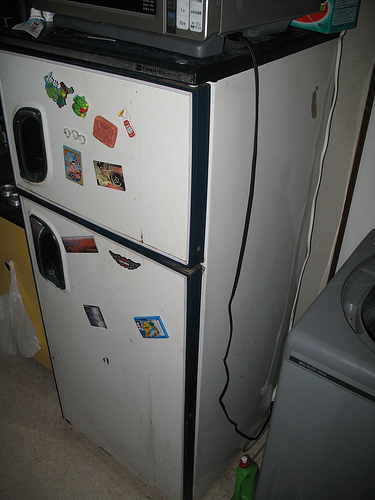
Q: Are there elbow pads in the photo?
A: No, there are no elbow pads.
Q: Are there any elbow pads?
A: No, there are no elbow pads.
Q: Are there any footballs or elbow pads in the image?
A: No, there are no elbow pads or footballs.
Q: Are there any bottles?
A: Yes, there is a bottle.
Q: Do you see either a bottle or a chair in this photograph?
A: Yes, there is a bottle.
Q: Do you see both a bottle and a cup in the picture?
A: No, there is a bottle but no cups.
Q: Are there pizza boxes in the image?
A: No, there are no pizza boxes.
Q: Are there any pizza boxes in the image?
A: No, there are no pizza boxes.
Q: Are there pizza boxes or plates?
A: No, there are no pizza boxes or plates.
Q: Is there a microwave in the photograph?
A: Yes, there is a microwave.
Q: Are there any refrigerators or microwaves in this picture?
A: Yes, there is a microwave.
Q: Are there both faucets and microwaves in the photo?
A: No, there is a microwave but no faucets.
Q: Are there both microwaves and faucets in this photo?
A: No, there is a microwave but no faucets.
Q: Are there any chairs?
A: No, there are no chairs.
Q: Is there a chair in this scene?
A: No, there are no chairs.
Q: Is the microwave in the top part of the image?
A: Yes, the microwave is in the top of the image.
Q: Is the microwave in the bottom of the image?
A: No, the microwave is in the top of the image.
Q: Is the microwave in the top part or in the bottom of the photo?
A: The microwave is in the top of the image.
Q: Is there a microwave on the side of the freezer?
A: Yes, there is a microwave on the side of the freezer.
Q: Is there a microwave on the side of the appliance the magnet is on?
A: Yes, there is a microwave on the side of the freezer.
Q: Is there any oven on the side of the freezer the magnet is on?
A: No, there is a microwave on the side of the refrigerator.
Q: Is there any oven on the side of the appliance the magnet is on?
A: No, there is a microwave on the side of the refrigerator.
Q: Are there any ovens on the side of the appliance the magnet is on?
A: No, there is a microwave on the side of the refrigerator.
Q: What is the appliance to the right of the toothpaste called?
A: The appliance is a microwave.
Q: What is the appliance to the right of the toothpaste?
A: The appliance is a microwave.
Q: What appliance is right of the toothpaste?
A: The appliance is a microwave.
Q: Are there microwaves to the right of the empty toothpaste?
A: Yes, there is a microwave to the right of the toothpaste.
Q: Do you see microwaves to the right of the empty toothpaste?
A: Yes, there is a microwave to the right of the toothpaste.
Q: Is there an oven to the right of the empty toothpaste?
A: No, there is a microwave to the right of the toothpaste.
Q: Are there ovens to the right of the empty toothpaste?
A: No, there is a microwave to the right of the toothpaste.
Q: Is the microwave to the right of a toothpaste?
A: Yes, the microwave is to the right of a toothpaste.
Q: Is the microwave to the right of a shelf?
A: No, the microwave is to the right of a toothpaste.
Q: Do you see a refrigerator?
A: Yes, there is a refrigerator.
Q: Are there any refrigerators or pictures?
A: Yes, there is a refrigerator.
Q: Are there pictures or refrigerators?
A: Yes, there is a refrigerator.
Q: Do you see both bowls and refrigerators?
A: No, there is a refrigerator but no bowls.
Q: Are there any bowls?
A: No, there are no bowls.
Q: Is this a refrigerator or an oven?
A: This is a refrigerator.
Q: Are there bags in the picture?
A: Yes, there is a bag.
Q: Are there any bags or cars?
A: Yes, there is a bag.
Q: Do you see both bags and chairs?
A: No, there is a bag but no chairs.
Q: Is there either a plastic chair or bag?
A: Yes, there is a plastic bag.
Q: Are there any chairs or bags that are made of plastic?
A: Yes, the bag is made of plastic.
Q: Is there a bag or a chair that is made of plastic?
A: Yes, the bag is made of plastic.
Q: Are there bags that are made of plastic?
A: Yes, there is a bag that is made of plastic.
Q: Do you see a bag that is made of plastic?
A: Yes, there is a bag that is made of plastic.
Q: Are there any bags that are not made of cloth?
A: Yes, there is a bag that is made of plastic.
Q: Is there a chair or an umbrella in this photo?
A: No, there are no chairs or umbrellas.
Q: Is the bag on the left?
A: Yes, the bag is on the left of the image.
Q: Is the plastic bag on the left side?
A: Yes, the bag is on the left of the image.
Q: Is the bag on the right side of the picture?
A: No, the bag is on the left of the image.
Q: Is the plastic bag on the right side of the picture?
A: No, the bag is on the left of the image.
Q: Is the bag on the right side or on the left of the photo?
A: The bag is on the left of the image.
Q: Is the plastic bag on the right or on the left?
A: The bag is on the left of the image.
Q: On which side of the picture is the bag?
A: The bag is on the left of the image.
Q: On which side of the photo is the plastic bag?
A: The bag is on the left of the image.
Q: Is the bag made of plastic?
A: Yes, the bag is made of plastic.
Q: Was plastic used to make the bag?
A: Yes, the bag is made of plastic.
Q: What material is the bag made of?
A: The bag is made of plastic.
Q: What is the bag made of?
A: The bag is made of plastic.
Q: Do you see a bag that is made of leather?
A: No, there is a bag but it is made of plastic.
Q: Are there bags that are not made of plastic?
A: No, there is a bag but it is made of plastic.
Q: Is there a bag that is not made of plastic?
A: No, there is a bag but it is made of plastic.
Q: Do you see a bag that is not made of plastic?
A: No, there is a bag but it is made of plastic.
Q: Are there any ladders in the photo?
A: No, there are no ladders.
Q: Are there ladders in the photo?
A: No, there are no ladders.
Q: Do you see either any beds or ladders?
A: No, there are no ladders or beds.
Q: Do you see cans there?
A: No, there are no cans.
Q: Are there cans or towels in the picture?
A: No, there are no cans or towels.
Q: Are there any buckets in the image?
A: No, there are no buckets.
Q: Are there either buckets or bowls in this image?
A: No, there are no buckets or bowls.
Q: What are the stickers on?
A: The stickers are on the freezer.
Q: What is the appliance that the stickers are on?
A: The appliance is a refrigerator.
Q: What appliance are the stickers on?
A: The stickers are on the refrigerator.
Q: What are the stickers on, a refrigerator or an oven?
A: The stickers are on a refrigerator.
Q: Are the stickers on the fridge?
A: Yes, the stickers are on the fridge.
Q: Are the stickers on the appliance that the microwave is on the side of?
A: Yes, the stickers are on the fridge.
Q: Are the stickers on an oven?
A: No, the stickers are on the fridge.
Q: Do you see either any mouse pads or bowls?
A: No, there are no bowls or mouse pads.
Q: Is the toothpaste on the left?
A: Yes, the toothpaste is on the left of the image.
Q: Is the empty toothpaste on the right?
A: No, the toothpaste is on the left of the image.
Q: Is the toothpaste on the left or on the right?
A: The toothpaste is on the left of the image.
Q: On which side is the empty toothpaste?
A: The toothpaste is on the left of the image.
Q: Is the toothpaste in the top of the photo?
A: Yes, the toothpaste is in the top of the image.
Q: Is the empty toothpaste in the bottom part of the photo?
A: No, the toothpaste is in the top of the image.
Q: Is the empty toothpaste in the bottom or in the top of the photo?
A: The toothpaste is in the top of the image.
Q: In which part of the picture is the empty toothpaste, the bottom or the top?
A: The toothpaste is in the top of the image.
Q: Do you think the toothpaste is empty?
A: Yes, the toothpaste is empty.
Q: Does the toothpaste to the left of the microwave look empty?
A: Yes, the toothpaste is empty.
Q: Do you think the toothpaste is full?
A: No, the toothpaste is empty.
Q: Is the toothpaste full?
A: No, the toothpaste is empty.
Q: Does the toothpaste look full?
A: No, the toothpaste is empty.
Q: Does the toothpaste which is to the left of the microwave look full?
A: No, the toothpaste is empty.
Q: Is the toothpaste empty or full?
A: The toothpaste is empty.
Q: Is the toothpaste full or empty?
A: The toothpaste is empty.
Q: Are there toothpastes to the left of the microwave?
A: Yes, there is a toothpaste to the left of the microwave.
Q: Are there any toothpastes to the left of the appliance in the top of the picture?
A: Yes, there is a toothpaste to the left of the microwave.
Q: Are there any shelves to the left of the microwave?
A: No, there is a toothpaste to the left of the microwave.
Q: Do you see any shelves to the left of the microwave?
A: No, there is a toothpaste to the left of the microwave.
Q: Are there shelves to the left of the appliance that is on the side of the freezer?
A: No, there is a toothpaste to the left of the microwave.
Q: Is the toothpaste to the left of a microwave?
A: Yes, the toothpaste is to the left of a microwave.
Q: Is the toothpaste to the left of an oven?
A: No, the toothpaste is to the left of a microwave.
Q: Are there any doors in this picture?
A: Yes, there is a door.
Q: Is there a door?
A: Yes, there is a door.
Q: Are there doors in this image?
A: Yes, there is a door.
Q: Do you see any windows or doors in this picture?
A: Yes, there is a door.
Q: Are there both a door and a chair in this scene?
A: No, there is a door but no chairs.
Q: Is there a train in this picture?
A: No, there are no trains.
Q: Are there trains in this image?
A: No, there are no trains.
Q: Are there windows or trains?
A: No, there are no trains or windows.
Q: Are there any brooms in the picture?
A: No, there are no brooms.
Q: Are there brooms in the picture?
A: No, there are no brooms.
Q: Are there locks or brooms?
A: No, there are no brooms or locks.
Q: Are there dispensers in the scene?
A: No, there are no dispensers.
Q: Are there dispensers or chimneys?
A: No, there are no dispensers or chimneys.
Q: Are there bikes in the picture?
A: No, there are no bikes.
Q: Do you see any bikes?
A: No, there are no bikes.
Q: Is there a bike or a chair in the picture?
A: No, there are no bikes or chairs.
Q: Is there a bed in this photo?
A: No, there are no beds.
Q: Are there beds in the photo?
A: No, there are no beds.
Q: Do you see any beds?
A: No, there are no beds.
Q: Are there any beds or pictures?
A: No, there are no beds or pictures.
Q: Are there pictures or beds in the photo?
A: No, there are no beds or pictures.